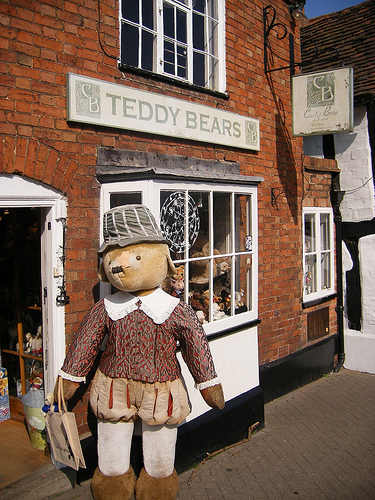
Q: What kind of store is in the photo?
A: Teddy Bear store.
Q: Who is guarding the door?
A: A teddy bear.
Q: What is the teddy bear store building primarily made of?
A: Brick.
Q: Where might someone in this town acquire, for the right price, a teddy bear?
A: Teddy Bears shop.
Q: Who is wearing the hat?
A: A teddy bear.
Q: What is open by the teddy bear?
A: The door to the shop.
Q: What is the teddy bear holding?
A: A bag.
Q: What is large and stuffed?
A: A teddy bear.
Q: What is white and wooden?
A: A door frame.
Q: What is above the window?
A: A sign.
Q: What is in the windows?
A: A bunch of stuffed teddy bears.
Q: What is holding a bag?
A: A teddy bear.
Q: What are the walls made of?
A: Brick,.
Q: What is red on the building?
A: The bricks.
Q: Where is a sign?
A: Front of the building.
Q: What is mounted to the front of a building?
A: A sign.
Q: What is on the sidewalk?
A: A stick.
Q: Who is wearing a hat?
A: A teddy bear.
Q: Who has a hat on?
A: A bear.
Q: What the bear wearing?
A: A shirt.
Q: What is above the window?
A: Words.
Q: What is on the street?
A: A human sized teddy bear.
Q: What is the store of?
A: Teddy bear and a gift shop.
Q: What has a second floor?
A: The building.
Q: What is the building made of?
A: Brick.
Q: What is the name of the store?
A: Teddy Bears.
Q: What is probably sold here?
A: Teddy bears.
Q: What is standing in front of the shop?
A: Teddy bear.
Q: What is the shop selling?
A: Teddy bears.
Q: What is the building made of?
A: Brick.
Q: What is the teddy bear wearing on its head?
A: A hat.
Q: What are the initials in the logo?
A: CB.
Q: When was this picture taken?
A: During the day.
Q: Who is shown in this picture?
A: Teddy bear.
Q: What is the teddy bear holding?
A: A bag.